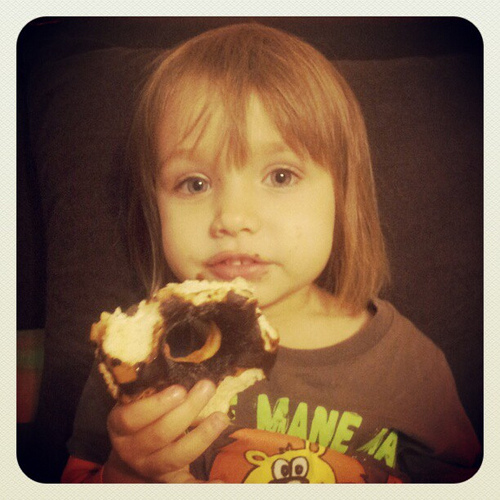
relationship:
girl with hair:
[64, 25, 480, 499] [116, 21, 392, 319]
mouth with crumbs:
[202, 245, 275, 279] [193, 271, 205, 283]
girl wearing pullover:
[64, 25, 480, 499] [75, 279, 481, 493]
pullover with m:
[75, 279, 481, 493] [250, 393, 290, 439]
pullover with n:
[75, 279, 481, 493] [310, 402, 339, 457]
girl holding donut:
[64, 25, 480, 499] [87, 273, 280, 437]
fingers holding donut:
[155, 409, 228, 473] [87, 273, 280, 437]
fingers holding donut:
[134, 377, 219, 461] [87, 273, 280, 437]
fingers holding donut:
[110, 384, 190, 442] [87, 273, 280, 437]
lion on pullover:
[209, 424, 371, 486] [75, 279, 481, 493]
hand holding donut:
[99, 375, 228, 484] [87, 273, 280, 437]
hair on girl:
[116, 21, 392, 319] [64, 25, 480, 499]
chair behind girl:
[29, 46, 483, 482] [64, 25, 480, 499]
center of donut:
[161, 314, 225, 367] [87, 273, 280, 437]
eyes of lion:
[271, 455, 309, 482] [209, 424, 371, 486]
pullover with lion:
[75, 279, 481, 493] [209, 424, 371, 486]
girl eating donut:
[64, 25, 480, 499] [87, 273, 280, 437]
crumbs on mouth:
[193, 271, 205, 283] [202, 245, 275, 279]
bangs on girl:
[156, 62, 326, 166] [64, 25, 480, 499]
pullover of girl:
[75, 279, 481, 493] [64, 25, 480, 499]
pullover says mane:
[75, 279, 481, 493] [252, 390, 362, 458]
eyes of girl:
[169, 171, 212, 198] [64, 25, 480, 499]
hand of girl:
[99, 375, 228, 484] [64, 25, 480, 499]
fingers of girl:
[155, 409, 228, 473] [64, 25, 480, 499]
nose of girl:
[207, 177, 263, 238] [64, 25, 480, 499]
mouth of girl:
[202, 245, 275, 279] [64, 25, 480, 499]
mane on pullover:
[252, 390, 362, 458] [75, 279, 481, 493]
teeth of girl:
[224, 258, 253, 268] [64, 25, 480, 499]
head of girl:
[134, 24, 353, 315] [64, 25, 480, 499]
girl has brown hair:
[64, 25, 480, 499] [107, 19, 399, 326]